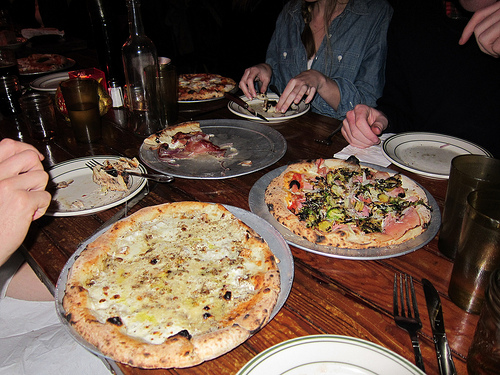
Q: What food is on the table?
A: Pizza.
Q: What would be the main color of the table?
A: Brown.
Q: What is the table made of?
A: Wood.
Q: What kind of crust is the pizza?
A: Thin crust.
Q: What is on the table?
A: Food.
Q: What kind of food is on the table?
A: Pizza.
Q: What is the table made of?
A: Wood.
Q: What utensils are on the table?
A: Fork and knife.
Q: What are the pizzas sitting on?
A: Round circular tin pans.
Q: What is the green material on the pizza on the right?
A: Vegetables.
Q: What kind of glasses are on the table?
A: Brown tinted transparent drinking glasses.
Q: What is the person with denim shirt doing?
A: Using fingers to eat food.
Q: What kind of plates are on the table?
A: White round plates with blue accents.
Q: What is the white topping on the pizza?
A: Cheese.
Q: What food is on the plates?
A: Pizza.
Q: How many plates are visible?
A: 8.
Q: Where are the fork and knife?
A: On the table.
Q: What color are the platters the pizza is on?
A: Silver.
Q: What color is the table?
A: Brown.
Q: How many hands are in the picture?
A: 5.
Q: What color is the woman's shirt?
A: Blue.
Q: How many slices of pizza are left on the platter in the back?
A: 1.